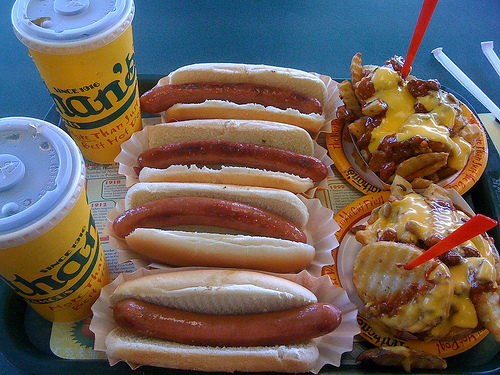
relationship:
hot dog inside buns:
[145, 83, 318, 105] [156, 63, 326, 123]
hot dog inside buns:
[147, 144, 326, 179] [150, 119, 317, 190]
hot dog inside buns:
[131, 201, 289, 232] [121, 183, 314, 268]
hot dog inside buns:
[116, 301, 340, 343] [112, 271, 318, 368]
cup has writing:
[15, 4, 144, 164] [50, 66, 142, 135]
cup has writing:
[5, 122, 102, 333] [15, 223, 107, 305]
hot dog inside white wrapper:
[145, 83, 318, 105] [149, 60, 341, 131]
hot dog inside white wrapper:
[147, 144, 326, 179] [107, 123, 336, 195]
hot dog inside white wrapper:
[131, 201, 289, 232] [100, 197, 343, 263]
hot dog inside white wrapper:
[116, 301, 340, 343] [87, 265, 365, 374]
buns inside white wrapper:
[156, 63, 326, 123] [149, 60, 341, 131]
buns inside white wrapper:
[150, 119, 317, 190] [107, 123, 336, 195]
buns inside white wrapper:
[121, 183, 314, 268] [100, 197, 343, 263]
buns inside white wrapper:
[112, 271, 318, 368] [87, 265, 365, 374]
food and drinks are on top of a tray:
[59, 94, 470, 346] [8, 63, 497, 374]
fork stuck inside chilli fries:
[400, 0, 439, 84] [345, 63, 469, 181]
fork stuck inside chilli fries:
[401, 215, 498, 280] [360, 208, 493, 334]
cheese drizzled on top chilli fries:
[384, 88, 410, 121] [345, 63, 469, 181]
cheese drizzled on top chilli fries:
[402, 206, 424, 224] [360, 208, 493, 334]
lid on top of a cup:
[11, 0, 134, 54] [15, 4, 144, 164]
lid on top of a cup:
[1, 113, 87, 244] [5, 122, 102, 333]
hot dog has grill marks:
[145, 83, 318, 105] [173, 84, 221, 95]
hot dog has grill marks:
[147, 144, 326, 179] [179, 145, 219, 155]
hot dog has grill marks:
[131, 201, 289, 232] [134, 208, 185, 228]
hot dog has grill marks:
[116, 301, 340, 343] [121, 314, 151, 337]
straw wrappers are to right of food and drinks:
[433, 35, 499, 134] [59, 94, 470, 346]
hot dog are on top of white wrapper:
[145, 83, 318, 105] [149, 60, 341, 131]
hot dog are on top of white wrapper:
[147, 144, 326, 179] [107, 123, 336, 195]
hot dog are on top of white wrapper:
[131, 201, 289, 232] [100, 197, 343, 263]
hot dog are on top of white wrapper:
[116, 301, 340, 343] [87, 265, 365, 374]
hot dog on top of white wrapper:
[145, 83, 318, 105] [149, 60, 341, 131]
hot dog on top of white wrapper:
[147, 144, 326, 179] [107, 123, 336, 195]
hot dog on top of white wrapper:
[131, 201, 289, 232] [100, 197, 343, 263]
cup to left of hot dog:
[15, 4, 144, 164] [111, 194, 308, 245]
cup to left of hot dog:
[5, 122, 102, 333] [111, 194, 308, 245]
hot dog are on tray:
[111, 194, 308, 245] [8, 63, 497, 374]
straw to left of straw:
[433, 50, 499, 123] [476, 37, 500, 84]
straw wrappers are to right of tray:
[433, 35, 499, 134] [8, 63, 497, 374]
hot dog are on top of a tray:
[111, 194, 308, 245] [8, 63, 497, 374]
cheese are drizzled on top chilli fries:
[384, 88, 410, 121] [345, 63, 469, 181]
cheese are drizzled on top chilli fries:
[402, 206, 424, 224] [360, 208, 493, 334]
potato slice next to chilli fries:
[353, 247, 445, 330] [360, 208, 493, 334]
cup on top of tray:
[15, 4, 144, 164] [8, 63, 497, 374]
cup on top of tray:
[5, 122, 102, 333] [8, 63, 497, 374]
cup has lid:
[15, 4, 144, 164] [11, 0, 134, 54]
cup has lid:
[5, 122, 102, 333] [1, 113, 87, 244]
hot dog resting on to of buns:
[145, 83, 318, 105] [156, 63, 326, 123]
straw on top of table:
[433, 50, 499, 123] [1, 2, 499, 374]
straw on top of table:
[476, 37, 500, 84] [1, 2, 499, 374]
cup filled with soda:
[15, 4, 144, 164] [34, 16, 49, 28]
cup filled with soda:
[5, 122, 102, 333] [34, 16, 49, 28]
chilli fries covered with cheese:
[345, 63, 469, 181] [384, 88, 410, 121]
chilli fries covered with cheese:
[360, 208, 493, 334] [402, 206, 424, 224]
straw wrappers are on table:
[433, 35, 499, 134] [1, 2, 499, 374]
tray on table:
[8, 63, 497, 374] [1, 2, 499, 374]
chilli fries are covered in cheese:
[345, 63, 469, 181] [384, 88, 410, 121]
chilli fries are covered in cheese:
[360, 208, 493, 334] [402, 206, 424, 224]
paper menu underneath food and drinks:
[63, 122, 411, 359] [59, 94, 470, 346]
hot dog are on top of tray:
[111, 194, 308, 245] [8, 63, 497, 374]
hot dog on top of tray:
[145, 83, 318, 105] [8, 63, 497, 374]